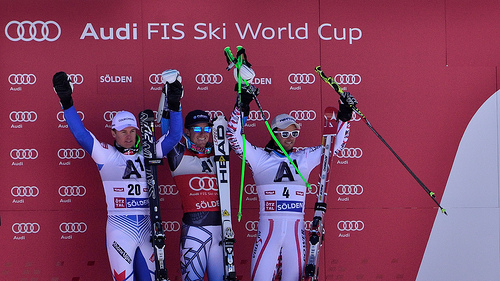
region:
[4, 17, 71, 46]
4 rings linked together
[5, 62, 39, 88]
4 rings linked together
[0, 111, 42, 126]
4 rings linked together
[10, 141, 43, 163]
4 rings linked together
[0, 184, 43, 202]
4 rings linked together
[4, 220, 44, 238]
4 rings linked together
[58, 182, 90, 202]
4 rings linked together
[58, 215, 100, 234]
4 rings linked together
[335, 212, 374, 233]
4 rings linked together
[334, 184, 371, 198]
4 rings linked together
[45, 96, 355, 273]
three people against wall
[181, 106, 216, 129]
man has black hat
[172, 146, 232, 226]
red and grey top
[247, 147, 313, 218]
black and white top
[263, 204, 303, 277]
red and white pants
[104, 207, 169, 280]
red white and blue pants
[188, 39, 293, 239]
man holds green poles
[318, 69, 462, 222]
yellow and black pole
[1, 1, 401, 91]
red and white wall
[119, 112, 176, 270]
black and white skis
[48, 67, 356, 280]
Ski player's raising their hands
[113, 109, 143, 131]
White cap on the person's head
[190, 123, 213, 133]
Shades of the person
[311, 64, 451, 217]
Ski pole held by a person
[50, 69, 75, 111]
black gloves on the person's right hand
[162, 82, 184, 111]
Black gloves on the person's left hand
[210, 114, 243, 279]
Ski board carried by a person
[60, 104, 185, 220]
Ski sport wear worn by a person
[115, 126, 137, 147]
Person's face smiling at the camera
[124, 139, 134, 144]
mouth of the person